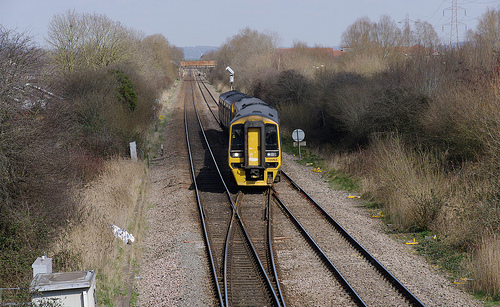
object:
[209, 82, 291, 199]
train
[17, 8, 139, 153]
trees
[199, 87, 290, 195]
tracks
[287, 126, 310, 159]
sign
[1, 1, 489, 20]
gray sky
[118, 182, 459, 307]
land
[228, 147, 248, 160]
lights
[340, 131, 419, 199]
green grass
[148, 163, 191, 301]
gravel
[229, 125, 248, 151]
windows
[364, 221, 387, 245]
debris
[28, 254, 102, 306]
box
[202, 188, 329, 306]
rail tracks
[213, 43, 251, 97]
smoke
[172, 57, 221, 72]
bridge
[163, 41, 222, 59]
mountain range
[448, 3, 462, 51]
pole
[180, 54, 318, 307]
train tracks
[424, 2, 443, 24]
power lines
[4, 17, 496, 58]
background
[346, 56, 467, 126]
shrubs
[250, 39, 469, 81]
houses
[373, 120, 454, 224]
grass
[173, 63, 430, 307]
railroad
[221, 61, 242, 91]
light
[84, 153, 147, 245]
underbrush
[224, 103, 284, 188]
car